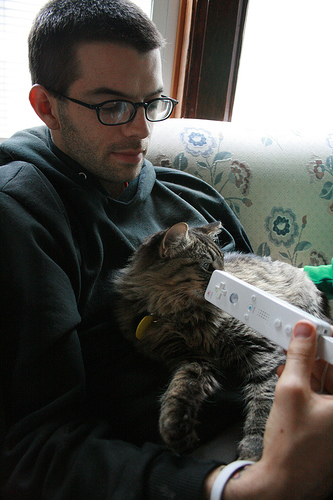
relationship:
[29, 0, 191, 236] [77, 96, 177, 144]
man wearing eyeglass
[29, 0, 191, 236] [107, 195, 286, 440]
man with cat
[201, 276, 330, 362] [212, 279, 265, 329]
controller has buttons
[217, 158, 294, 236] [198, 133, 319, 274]
flowers on sofa